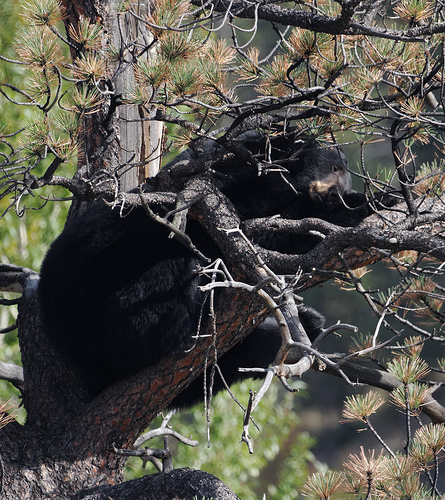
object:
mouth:
[309, 181, 333, 208]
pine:
[64, 86, 105, 115]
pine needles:
[339, 335, 441, 425]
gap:
[133, 35, 150, 186]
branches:
[125, 0, 443, 49]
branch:
[0, 0, 445, 456]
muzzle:
[303, 148, 352, 210]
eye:
[332, 165, 337, 173]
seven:
[239, 389, 257, 454]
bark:
[0, 441, 124, 500]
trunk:
[0, 344, 238, 500]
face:
[309, 148, 357, 211]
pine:
[132, 29, 209, 92]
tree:
[0, 0, 445, 500]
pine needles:
[68, 17, 106, 50]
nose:
[331, 185, 342, 196]